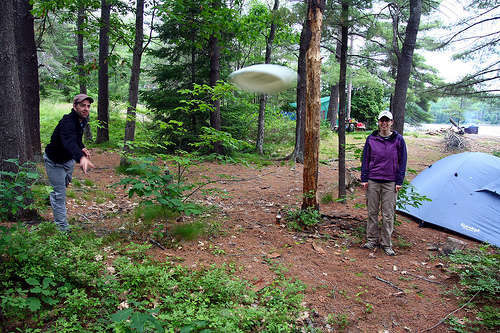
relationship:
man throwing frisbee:
[40, 91, 98, 238] [225, 61, 295, 96]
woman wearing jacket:
[358, 111, 409, 255] [361, 131, 408, 185]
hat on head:
[376, 112, 396, 122] [376, 111, 394, 133]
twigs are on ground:
[371, 269, 442, 300] [7, 126, 494, 332]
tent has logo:
[396, 151, 499, 253] [459, 222, 482, 234]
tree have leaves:
[120, 82, 248, 233] [122, 84, 263, 174]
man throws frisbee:
[40, 91, 98, 238] [225, 61, 295, 96]